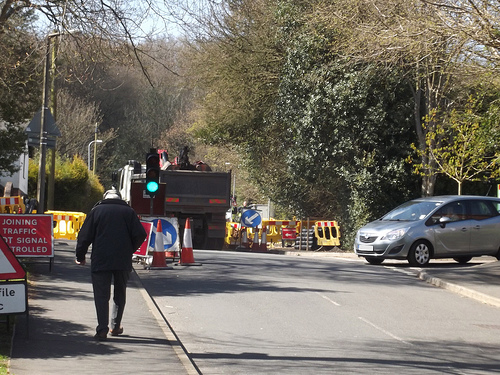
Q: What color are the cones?
A: White and Orange.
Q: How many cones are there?
A: 2.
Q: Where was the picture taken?
A: On a street.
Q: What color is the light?
A: Green.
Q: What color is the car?
A: Gray.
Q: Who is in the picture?
A: A man.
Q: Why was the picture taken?
A: To show the street.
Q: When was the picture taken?
A: In the daytime.